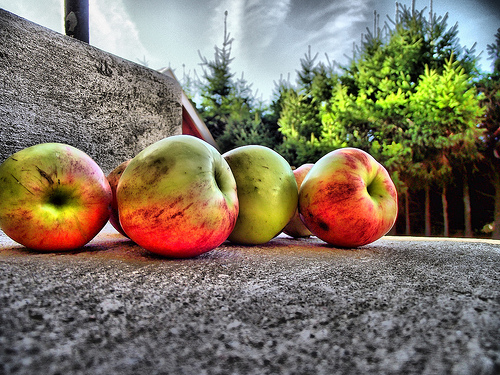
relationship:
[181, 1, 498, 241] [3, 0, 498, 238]
trees in background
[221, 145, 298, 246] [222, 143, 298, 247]
apple has skin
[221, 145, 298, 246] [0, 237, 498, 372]
apple on ground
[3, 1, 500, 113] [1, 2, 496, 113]
clouds in sky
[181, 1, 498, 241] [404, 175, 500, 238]
trees have trunks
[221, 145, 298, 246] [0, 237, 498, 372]
apple laying on ground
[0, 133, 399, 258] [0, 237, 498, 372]
apples on ground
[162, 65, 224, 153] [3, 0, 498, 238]
roof in background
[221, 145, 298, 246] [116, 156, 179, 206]
apple has marks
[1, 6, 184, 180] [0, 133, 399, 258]
wall behind apples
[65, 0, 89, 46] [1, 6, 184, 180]
pipe out of wall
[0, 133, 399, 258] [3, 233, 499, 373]
apples on stone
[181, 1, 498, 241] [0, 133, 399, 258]
trees behind apples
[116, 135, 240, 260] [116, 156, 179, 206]
apple has marks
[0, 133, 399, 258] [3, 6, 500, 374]
apples on bench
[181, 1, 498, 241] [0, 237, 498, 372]
trees beside ground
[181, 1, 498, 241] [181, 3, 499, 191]
trees have leaves